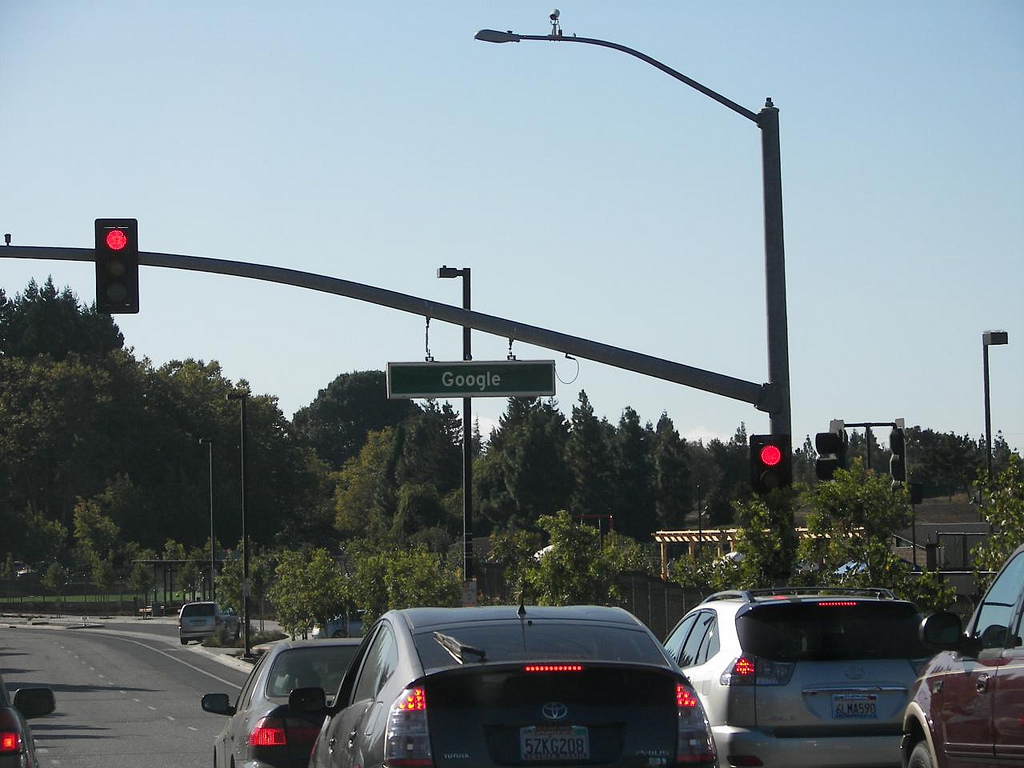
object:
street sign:
[380, 351, 560, 401]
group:
[198, 577, 989, 765]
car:
[315, 585, 719, 767]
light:
[244, 710, 296, 761]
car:
[172, 606, 341, 754]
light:
[398, 683, 432, 714]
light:
[673, 725, 716, 764]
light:
[800, 574, 876, 620]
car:
[304, 597, 728, 767]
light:
[514, 655, 593, 677]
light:
[397, 688, 430, 712]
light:
[665, 683, 705, 711]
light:
[715, 656, 762, 682]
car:
[659, 581, 942, 747]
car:
[172, 595, 236, 646]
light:
[205, 611, 236, 629]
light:
[176, 617, 192, 648]